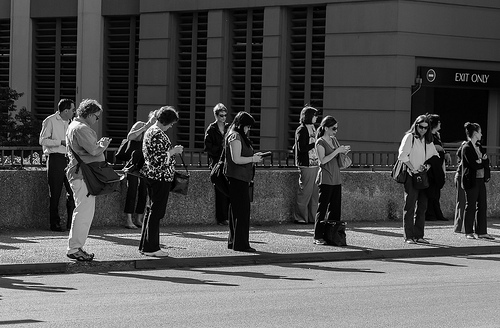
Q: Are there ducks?
A: No, there are no ducks.